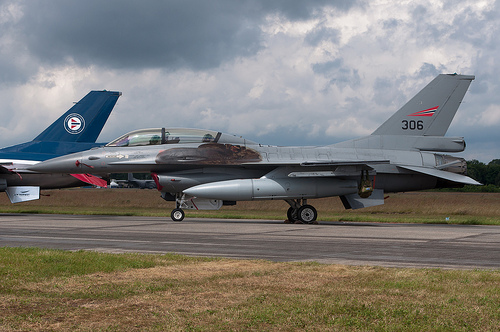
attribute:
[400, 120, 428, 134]
number — 306, blue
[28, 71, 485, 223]
plane — gray, parked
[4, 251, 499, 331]
grass — dry, green, brown, short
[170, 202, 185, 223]
wheel — small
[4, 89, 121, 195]
plane — blue, parked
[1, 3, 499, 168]
sky — blue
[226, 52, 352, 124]
cloud — dark, white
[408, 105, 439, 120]
design — red